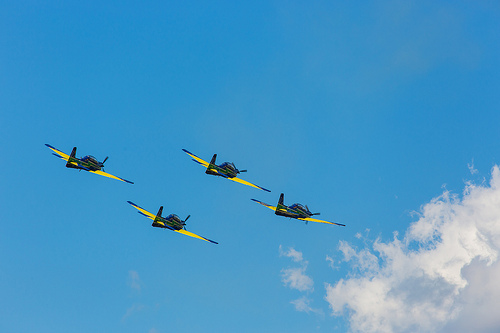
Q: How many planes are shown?
A: 4.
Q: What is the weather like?
A: Partly cloudy.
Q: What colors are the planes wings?
A: Yellow and blue.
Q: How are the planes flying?
A: In formation.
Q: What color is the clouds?
A: White.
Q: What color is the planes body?
A: Blue.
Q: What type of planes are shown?
A: Single propellers.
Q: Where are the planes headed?
A: Away from the camera.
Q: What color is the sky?
A: Blue.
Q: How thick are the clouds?
A: Sparse.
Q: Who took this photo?
A: An onlooker.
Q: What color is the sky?
A: It is blue.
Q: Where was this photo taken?
A: In the sky.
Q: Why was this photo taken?
A: To capture the air craft show.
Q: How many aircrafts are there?
A: There are 4.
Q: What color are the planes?
A: They are blue and yellow.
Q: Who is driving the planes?
A: The pilots.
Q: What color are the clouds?
A: They are white.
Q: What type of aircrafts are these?
A: Military.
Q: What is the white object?
A: A cloud.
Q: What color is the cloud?
A: White.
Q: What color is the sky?
A: Blue.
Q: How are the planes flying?
A: In formation.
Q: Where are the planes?
A: In the sky.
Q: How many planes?
A: 4.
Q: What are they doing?
A: Flying.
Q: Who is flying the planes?
A: Pilots.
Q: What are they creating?
A: Formation.